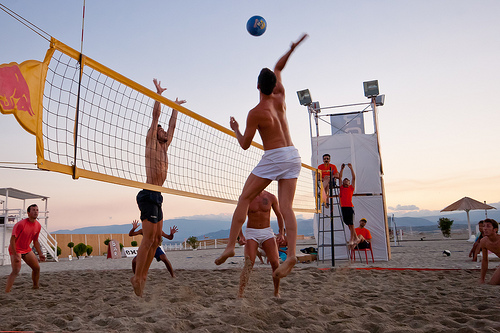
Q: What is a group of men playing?
A: Volleyball.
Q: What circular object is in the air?
A: Volleyball.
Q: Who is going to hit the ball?
A: The man to the right.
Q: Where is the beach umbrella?
A: In the sand.